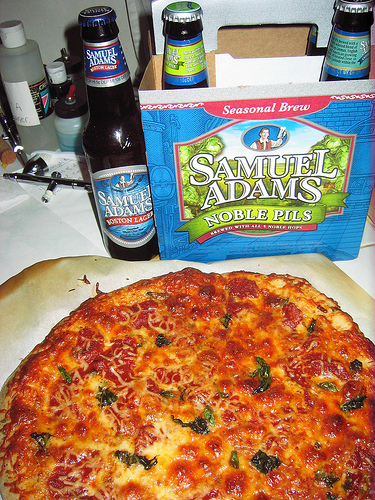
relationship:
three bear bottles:
[78, 38, 272, 127] [143, 6, 374, 94]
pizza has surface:
[16, 282, 368, 489] [97, 344, 295, 449]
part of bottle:
[68, 9, 162, 248] [69, 11, 172, 259]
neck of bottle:
[68, 11, 141, 96] [69, 11, 172, 259]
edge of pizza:
[108, 262, 327, 301] [16, 282, 368, 489]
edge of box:
[130, 84, 189, 262] [131, 49, 365, 251]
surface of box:
[172, 116, 349, 223] [131, 49, 365, 251]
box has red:
[131, 49, 365, 251] [210, 92, 351, 118]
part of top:
[68, 9, 162, 248] [75, 7, 136, 56]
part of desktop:
[14, 173, 106, 278] [12, 132, 374, 283]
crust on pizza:
[0, 299, 68, 401] [16, 282, 368, 489]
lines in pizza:
[91, 328, 176, 408] [16, 282, 368, 489]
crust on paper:
[0, 299, 68, 401] [0, 253, 97, 366]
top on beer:
[75, 7, 136, 56] [69, 11, 172, 259]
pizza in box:
[16, 282, 368, 489] [10, 261, 374, 425]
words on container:
[183, 150, 343, 217] [131, 49, 365, 251]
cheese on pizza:
[150, 340, 316, 445] [16, 282, 368, 489]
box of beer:
[131, 49, 365, 251] [143, 6, 374, 94]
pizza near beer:
[16, 282, 368, 489] [143, 6, 374, 94]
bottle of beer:
[69, 11, 172, 259] [143, 6, 374, 94]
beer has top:
[143, 6, 374, 94] [75, 7, 136, 56]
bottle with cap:
[6, 14, 68, 178] [0, 12, 31, 51]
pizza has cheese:
[16, 282, 368, 489] [150, 340, 316, 445]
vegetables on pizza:
[240, 345, 366, 449] [16, 282, 368, 489]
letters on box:
[183, 150, 343, 217] [131, 49, 365, 251]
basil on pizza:
[183, 399, 222, 438] [16, 282, 368, 489]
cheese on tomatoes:
[150, 340, 316, 445] [74, 351, 299, 476]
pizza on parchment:
[16, 282, 368, 489] [13, 250, 363, 366]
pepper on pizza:
[16, 451, 95, 500] [16, 282, 368, 489]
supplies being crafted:
[0, 25, 110, 171] [0, 12, 93, 173]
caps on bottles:
[1, 12, 76, 90] [7, 48, 74, 162]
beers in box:
[143, 6, 374, 94] [131, 49, 365, 251]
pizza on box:
[16, 282, 368, 489] [10, 261, 374, 425]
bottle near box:
[69, 11, 172, 259] [131, 49, 365, 251]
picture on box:
[185, 114, 370, 244] [131, 49, 365, 251]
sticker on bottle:
[85, 161, 162, 251] [69, 11, 172, 259]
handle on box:
[143, 5, 373, 60] [131, 49, 365, 251]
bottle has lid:
[6, 14, 68, 178] [0, 21, 47, 50]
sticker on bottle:
[2, 81, 45, 126] [6, 14, 68, 178]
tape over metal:
[36, 185, 61, 209] [16, 155, 84, 204]